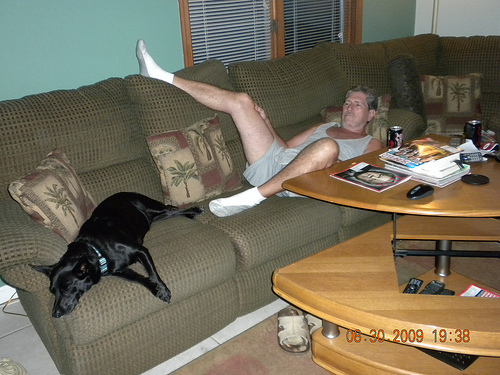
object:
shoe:
[304, 314, 322, 335]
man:
[134, 39, 383, 218]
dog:
[28, 191, 206, 318]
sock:
[208, 186, 267, 218]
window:
[178, 0, 360, 67]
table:
[270, 215, 500, 357]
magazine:
[377, 136, 465, 169]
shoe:
[277, 308, 312, 356]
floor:
[197, 341, 276, 372]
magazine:
[329, 161, 413, 193]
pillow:
[8, 147, 98, 243]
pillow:
[145, 113, 244, 208]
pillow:
[424, 115, 445, 132]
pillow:
[319, 94, 391, 145]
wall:
[0, 0, 118, 66]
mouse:
[406, 183, 435, 201]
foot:
[134, 39, 275, 165]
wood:
[276, 271, 343, 288]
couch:
[0, 32, 500, 373]